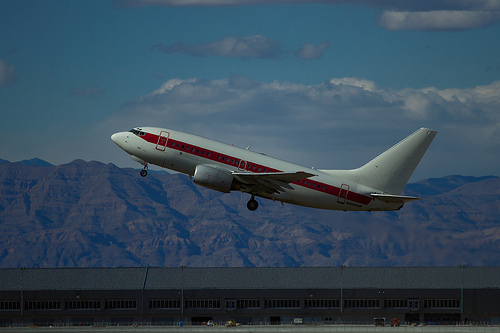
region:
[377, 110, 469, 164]
tail of the plane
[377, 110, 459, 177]
white tail of the plane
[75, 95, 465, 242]
red and white plane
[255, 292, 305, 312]
windows on the building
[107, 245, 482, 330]
long building on the ground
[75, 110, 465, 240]
plane in the air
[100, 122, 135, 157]
nose of the plane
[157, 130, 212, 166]
windows on the plane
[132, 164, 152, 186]
wheel on botton of plane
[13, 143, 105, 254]
mountains in the background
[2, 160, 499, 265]
Mountains beside the airplane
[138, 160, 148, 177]
The front wheel of the airplane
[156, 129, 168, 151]
A door on the side of the airplane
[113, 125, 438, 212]
An airplane in the air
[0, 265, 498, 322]
A building below the airplane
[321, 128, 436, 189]
The tail of the airplane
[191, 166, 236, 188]
The left engine of the airplane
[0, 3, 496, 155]
The sky above the airplane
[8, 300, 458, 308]
Windows on the side of the building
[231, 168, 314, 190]
The left wing of the airplane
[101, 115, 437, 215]
a plane flying away from the airport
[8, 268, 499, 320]
a long building near the runway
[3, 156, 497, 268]
a mountain next to the building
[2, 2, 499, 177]
the partially cloudy sky above everything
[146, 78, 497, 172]
a big cloud near the mountain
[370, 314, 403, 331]
some cars on the ground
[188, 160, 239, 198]
the engine on the left wing of the plane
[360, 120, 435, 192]
the tail of the airplane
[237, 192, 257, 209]
the wheel on the plane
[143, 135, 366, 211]
the red stripe on the plane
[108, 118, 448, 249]
plane is taking off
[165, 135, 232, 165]
windows are on the plane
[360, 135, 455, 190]
the tail is white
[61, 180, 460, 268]
hills are in the background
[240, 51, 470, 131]
clouds are in the sky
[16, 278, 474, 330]
building has many windows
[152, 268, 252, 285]
the roof is grey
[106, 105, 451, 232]
the plane is a commercial plane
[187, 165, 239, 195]
engine is beneath the wing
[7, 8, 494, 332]
it is daytime in the photo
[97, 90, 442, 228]
THE PLANE IS POINTED TOWARDS THE SKY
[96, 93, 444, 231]
THE PLANE IS TAKING OFF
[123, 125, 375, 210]
THE PLANE HAS MANY WINDOWS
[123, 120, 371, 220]
THIS IS A RED STRIPE ON THE PLANE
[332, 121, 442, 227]
THIS IS THE TAIL OF THE PLANE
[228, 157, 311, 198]
THIS IS THE WING OF THE PLANE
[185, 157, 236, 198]
THIS IS THE ENGINE ON THE PLANE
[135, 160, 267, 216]
THE LANDING GEAR IS DOWN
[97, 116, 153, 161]
THIS IS THE NOSE OF THE PLANE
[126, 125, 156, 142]
THIS IS THE PLANES WINDSHIELD